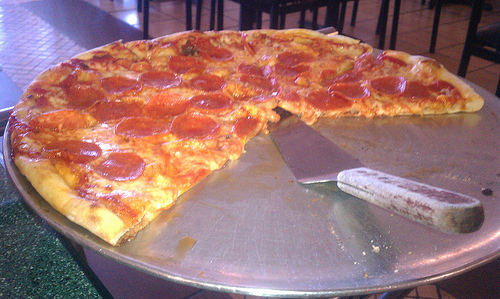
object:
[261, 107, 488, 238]
spatula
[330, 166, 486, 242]
wooden handle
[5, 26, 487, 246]
pizza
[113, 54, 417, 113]
cheese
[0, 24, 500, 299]
pizzatray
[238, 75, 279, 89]
redtoppings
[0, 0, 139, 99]
floor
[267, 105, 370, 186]
blade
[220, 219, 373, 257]
surface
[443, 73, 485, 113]
crust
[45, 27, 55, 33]
tiles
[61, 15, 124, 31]
shadow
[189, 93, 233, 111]
pepperoni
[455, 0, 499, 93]
chairs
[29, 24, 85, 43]
walkway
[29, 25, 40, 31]
bricks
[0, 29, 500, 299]
pan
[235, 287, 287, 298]
light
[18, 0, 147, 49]
carpet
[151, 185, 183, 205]
cheese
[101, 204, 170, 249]
edge of crust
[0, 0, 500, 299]
restaraunt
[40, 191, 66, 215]
pizzacrust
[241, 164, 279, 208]
pizzagrease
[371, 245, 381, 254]
crumbs